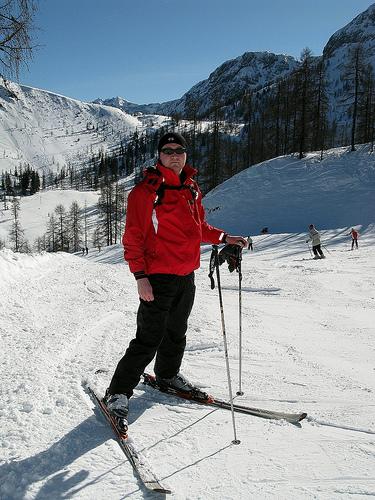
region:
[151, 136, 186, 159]
man has black cap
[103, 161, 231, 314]
man has red coat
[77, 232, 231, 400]
man has black pants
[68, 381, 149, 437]
man has black shoes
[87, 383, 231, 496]
red and black skis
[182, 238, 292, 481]
man holds white ski poles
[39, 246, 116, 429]
white and tracked snow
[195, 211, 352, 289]
people on hill behind man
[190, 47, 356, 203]
tall and thin trees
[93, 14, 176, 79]
sky is blue and clear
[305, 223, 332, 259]
a person skiing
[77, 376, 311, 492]
red skis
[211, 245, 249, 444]
ski poles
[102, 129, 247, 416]
a man skiing in the mountains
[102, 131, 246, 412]
a man wearing a red jacket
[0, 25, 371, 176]
mountains in the distance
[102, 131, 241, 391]
a man wearing sunglasses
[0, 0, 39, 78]
a branch of a tree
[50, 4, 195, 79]
the clear blue sky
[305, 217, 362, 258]
people skiing in the distance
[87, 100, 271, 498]
Person standing in the snow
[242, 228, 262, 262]
Person standing in the snow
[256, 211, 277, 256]
Person standing in the snow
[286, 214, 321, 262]
Person standing in the snow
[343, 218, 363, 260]
Person standing in the snow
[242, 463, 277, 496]
Snow covering the ground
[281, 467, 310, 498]
Snow covering the ground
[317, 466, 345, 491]
Snow covering the ground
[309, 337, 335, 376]
Snow covering the ground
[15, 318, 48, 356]
Snow covering the ground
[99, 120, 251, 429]
Man looking at camera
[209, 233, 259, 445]
Black and white ski poles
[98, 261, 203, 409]
black ski pants on man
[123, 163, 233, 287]
Red white and black ski jacket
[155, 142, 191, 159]
One pair of black snow goggles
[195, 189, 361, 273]
People skiing in the distance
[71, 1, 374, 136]
Mountains in the distance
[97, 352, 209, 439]
Black and gray snow shoes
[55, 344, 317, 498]
Two black snow skis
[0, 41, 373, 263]
A bunch of skinny green trees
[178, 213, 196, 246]
the coat is red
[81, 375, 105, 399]
the ski's have snow on them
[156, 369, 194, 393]
the boots are silver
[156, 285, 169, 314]
the pants are black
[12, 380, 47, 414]
the snow is clumpy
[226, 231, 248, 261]
he has his hand on the pole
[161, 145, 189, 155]
he is wearing sunglasses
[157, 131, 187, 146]
the hat is black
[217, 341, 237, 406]
the pole is white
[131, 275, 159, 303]
he is not wearing the gloves